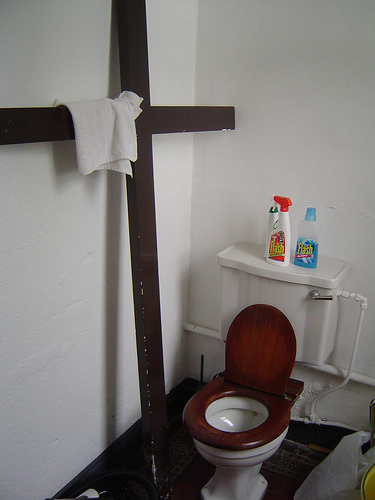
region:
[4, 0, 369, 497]
The inside of a restroom.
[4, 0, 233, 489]
A wood cross in the restroom.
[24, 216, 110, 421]
The wall is white.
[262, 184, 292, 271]
The spray bottle is orange and white.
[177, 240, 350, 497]
The toilet is white.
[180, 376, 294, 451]
The toilet seat is made out of wood.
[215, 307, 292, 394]
The toilet lid is made out of wood.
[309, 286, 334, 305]
The flusher on the toilet.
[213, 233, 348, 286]
The lid of the toilet tank.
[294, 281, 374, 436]
A white pipe connected to the toilet.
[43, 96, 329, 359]
a cross by a toilet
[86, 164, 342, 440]
this photo has been altered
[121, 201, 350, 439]
this photo is black and white with color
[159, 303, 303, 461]
this toilet seat is wooden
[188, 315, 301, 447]
this toliet seat is brown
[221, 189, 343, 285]
cleaning products on the toilet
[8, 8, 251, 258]
the cross on the wall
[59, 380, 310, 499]
a brown floor in the bathroom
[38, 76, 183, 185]
a towel on the cross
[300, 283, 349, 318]
a handle on a toilet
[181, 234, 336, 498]
toilet with wood seat and lid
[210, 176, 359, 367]
toilet tank with cleaning products on top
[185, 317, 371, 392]
white pipe on wall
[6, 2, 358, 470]
two walls painted white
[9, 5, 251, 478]
white towel draped on pole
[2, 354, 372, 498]
black baseboard on wall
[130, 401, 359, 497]
ornate tile on floor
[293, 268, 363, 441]
white pipe coming out of toilet tank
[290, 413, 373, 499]
white plastic bag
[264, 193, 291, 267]
white and red package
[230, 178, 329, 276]
bottles of cleanser on the toilet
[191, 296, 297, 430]
the toilet lid is up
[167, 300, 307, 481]
the toilet seat is brown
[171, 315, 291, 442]
the toilet seat is made of wood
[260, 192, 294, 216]
the top of the bottle is orange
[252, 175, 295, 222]
the style is a spray bottle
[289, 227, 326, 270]
the liquid in the bottle is blue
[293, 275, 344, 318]
the handle is silver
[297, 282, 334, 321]
the handle is made of metal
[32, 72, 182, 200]
the towel is white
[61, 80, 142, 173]
a towel in the photo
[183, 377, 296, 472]
A toilet seat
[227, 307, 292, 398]
A toilet lid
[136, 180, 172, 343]
A metal bar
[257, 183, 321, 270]
Disinfectants in the photo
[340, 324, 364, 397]
A pipe on the photo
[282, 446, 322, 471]
A carpet in the bathroom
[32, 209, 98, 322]
A concrete wall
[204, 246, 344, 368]
Toilet tank in the bathroom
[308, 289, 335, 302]
A metallic handle in the photo